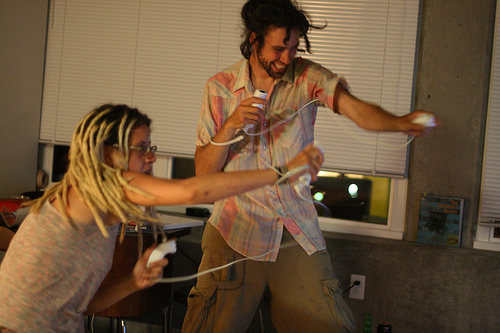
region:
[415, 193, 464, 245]
book on inside window ledge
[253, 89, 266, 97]
top of WI video game controler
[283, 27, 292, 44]
front part of male hair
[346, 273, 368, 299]
electric wall socket on wall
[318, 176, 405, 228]
bottom part of large window in room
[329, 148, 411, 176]
edge of white blinds in room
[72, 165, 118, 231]
blond dreadlocks of woman game player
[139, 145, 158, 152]
glasses on face of woman game player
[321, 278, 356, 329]
large pocket on pants of male game player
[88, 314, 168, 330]
bottom part of chair legs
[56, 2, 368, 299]
A man and a woman playing Wii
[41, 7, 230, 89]
White blinds on the window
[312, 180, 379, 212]
Glass window pane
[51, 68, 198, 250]
A woman wearing prescription glasses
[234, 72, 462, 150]
Wii remote control and nunchuk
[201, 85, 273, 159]
Wii remote control strap around the wrist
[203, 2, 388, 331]
A man wearing plaid shirt and cargo shorts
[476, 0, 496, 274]
Partially visible window in the room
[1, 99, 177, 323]
A woman wearing grey tank top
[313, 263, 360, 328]
Pocket on the shorts sleeves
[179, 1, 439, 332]
Young man has black hair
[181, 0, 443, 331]
Young man wearing plaid shirt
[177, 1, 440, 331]
Young man wearing khaki pants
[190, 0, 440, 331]
Young man holding white controller in left hand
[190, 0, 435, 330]
Young man holding white controller in right hand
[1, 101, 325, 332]
Woman wearing glasses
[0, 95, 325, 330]
Woman holding white controller in left hand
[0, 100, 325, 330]
Woman holding white controller in right hand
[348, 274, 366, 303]
White wall socket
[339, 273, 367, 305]
Black plug in white wall socket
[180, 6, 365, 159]
this is a man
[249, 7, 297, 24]
the hair is black in color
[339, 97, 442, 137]
the hand is in front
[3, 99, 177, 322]
this is a woman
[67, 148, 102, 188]
the hair is yellow in color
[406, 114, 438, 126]
this is a remote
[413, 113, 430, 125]
the remote is white in color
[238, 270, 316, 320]
he is wearing shorts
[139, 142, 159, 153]
she is wearing spectacles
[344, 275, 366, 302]
this is a socket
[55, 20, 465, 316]
A couple playing Wii together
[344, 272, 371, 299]
A white electrical outlet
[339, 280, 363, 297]
A small black cable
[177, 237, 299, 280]
A thin white wire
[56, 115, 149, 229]
Thick blonde dreadlocks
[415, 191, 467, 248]
A book near the window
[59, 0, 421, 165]
White blinds over the window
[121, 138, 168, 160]
Glasses on the woman's face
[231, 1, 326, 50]
The man has long hair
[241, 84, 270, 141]
A white Wii remote